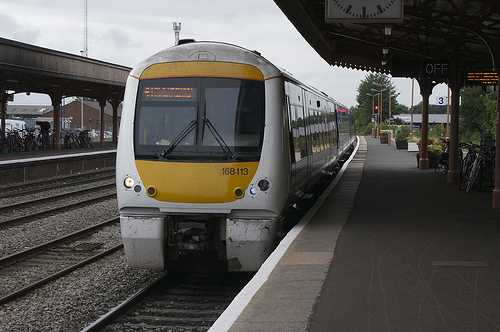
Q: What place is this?
A: It is a station.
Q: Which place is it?
A: It is a station.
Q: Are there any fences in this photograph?
A: No, there are no fences.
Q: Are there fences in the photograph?
A: No, there are no fences.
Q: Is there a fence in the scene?
A: No, there are no fences.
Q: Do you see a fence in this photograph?
A: No, there are no fences.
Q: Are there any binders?
A: No, there are no binders.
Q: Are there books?
A: No, there are no books.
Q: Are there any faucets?
A: No, there are no faucets.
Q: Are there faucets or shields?
A: No, there are no faucets or shields.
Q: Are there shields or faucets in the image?
A: No, there are no faucets or shields.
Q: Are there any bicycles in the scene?
A: Yes, there is a bicycle.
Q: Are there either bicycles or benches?
A: Yes, there is a bicycle.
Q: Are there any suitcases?
A: No, there are no suitcases.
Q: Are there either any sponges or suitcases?
A: No, there are no suitcases or sponges.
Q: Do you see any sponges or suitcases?
A: No, there are no suitcases or sponges.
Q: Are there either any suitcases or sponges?
A: No, there are no suitcases or sponges.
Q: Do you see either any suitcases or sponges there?
A: No, there are no suitcases or sponges.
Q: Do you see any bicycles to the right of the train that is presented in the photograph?
A: Yes, there is a bicycle to the right of the train.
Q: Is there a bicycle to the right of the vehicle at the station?
A: Yes, there is a bicycle to the right of the train.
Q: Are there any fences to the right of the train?
A: No, there is a bicycle to the right of the train.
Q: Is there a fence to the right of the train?
A: No, there is a bicycle to the right of the train.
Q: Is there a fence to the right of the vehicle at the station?
A: No, there is a bicycle to the right of the train.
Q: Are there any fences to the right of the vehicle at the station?
A: No, there is a bicycle to the right of the train.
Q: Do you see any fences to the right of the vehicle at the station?
A: No, there is a bicycle to the right of the train.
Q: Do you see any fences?
A: No, there are no fences.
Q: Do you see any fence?
A: No, there are no fences.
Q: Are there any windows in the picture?
A: Yes, there is a window.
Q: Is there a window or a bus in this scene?
A: Yes, there is a window.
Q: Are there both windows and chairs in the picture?
A: No, there is a window but no chairs.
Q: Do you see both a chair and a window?
A: No, there is a window but no chairs.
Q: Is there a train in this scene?
A: Yes, there is a train.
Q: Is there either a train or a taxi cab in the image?
A: Yes, there is a train.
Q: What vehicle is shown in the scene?
A: The vehicle is a train.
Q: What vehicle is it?
A: The vehicle is a train.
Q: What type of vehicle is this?
A: This is a train.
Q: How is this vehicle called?
A: This is a train.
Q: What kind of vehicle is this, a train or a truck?
A: This is a train.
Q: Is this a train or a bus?
A: This is a train.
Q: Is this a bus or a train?
A: This is a train.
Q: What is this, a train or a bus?
A: This is a train.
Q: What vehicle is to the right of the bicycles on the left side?
A: The vehicle is a train.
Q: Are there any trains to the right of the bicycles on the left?
A: Yes, there is a train to the right of the bicycles.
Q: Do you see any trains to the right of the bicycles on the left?
A: Yes, there is a train to the right of the bicycles.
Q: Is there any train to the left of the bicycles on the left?
A: No, the train is to the right of the bicycles.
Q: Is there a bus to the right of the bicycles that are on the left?
A: No, there is a train to the right of the bicycles.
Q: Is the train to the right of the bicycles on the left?
A: Yes, the train is to the right of the bicycles.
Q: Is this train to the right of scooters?
A: No, the train is to the right of the bicycles.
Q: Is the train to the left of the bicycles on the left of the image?
A: No, the train is to the right of the bicycles.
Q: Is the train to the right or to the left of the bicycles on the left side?
A: The train is to the right of the bicycles.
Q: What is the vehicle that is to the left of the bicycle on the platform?
A: The vehicle is a train.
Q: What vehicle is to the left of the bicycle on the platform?
A: The vehicle is a train.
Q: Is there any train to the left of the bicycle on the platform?
A: Yes, there is a train to the left of the bicycle.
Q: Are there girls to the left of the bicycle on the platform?
A: No, there is a train to the left of the bicycle.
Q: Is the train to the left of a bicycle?
A: Yes, the train is to the left of a bicycle.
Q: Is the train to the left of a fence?
A: No, the train is to the left of a bicycle.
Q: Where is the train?
A: The train is at the station.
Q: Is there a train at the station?
A: Yes, there is a train at the station.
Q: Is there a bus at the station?
A: No, there is a train at the station.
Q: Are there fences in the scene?
A: No, there are no fences.